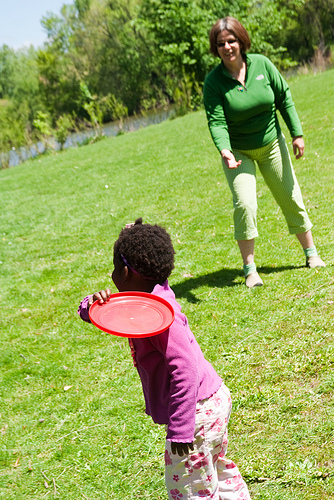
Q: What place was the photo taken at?
A: It was taken at the garden.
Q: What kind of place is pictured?
A: It is a garden.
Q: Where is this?
A: This is at the garden.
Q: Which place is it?
A: It is a garden.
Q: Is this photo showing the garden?
A: Yes, it is showing the garden.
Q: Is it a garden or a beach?
A: It is a garden.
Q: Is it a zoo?
A: No, it is a garden.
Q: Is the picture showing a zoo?
A: No, the picture is showing a garden.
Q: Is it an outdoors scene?
A: Yes, it is outdoors.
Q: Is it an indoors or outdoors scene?
A: It is outdoors.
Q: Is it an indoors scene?
A: No, it is outdoors.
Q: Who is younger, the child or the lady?
A: The child is younger than the lady.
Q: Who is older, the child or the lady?
A: The lady is older than the child.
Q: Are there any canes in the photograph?
A: No, there are no canes.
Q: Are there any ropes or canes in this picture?
A: No, there are no canes or ropes.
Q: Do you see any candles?
A: No, there are no candles.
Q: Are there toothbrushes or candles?
A: No, there are no candles or toothbrushes.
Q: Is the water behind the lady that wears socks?
A: Yes, the water is behind the lady.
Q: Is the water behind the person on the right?
A: Yes, the water is behind the lady.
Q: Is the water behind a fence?
A: No, the water is behind the lady.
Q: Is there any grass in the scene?
A: Yes, there is grass.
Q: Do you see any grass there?
A: Yes, there is grass.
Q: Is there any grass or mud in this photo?
A: Yes, there is grass.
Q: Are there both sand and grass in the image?
A: No, there is grass but no sand.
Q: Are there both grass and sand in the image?
A: No, there is grass but no sand.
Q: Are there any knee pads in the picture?
A: No, there are no knee pads.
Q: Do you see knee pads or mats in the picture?
A: No, there are no knee pads or mats.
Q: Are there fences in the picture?
A: No, there are no fences.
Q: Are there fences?
A: No, there are no fences.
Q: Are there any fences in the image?
A: No, there are no fences.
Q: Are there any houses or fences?
A: No, there are no fences or houses.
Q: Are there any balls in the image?
A: No, there are no balls.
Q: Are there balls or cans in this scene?
A: No, there are no balls or cans.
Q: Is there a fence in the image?
A: No, there are no fences.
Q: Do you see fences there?
A: No, there are no fences.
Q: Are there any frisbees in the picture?
A: Yes, there is a frisbee.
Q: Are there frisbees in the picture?
A: Yes, there is a frisbee.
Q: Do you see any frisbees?
A: Yes, there is a frisbee.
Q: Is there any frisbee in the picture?
A: Yes, there is a frisbee.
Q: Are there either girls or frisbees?
A: Yes, there is a frisbee.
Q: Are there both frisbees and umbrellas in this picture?
A: No, there is a frisbee but no umbrellas.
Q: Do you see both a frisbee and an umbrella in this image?
A: No, there is a frisbee but no umbrellas.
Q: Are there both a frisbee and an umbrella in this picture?
A: No, there is a frisbee but no umbrellas.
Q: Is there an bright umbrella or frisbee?
A: Yes, there is a bright frisbee.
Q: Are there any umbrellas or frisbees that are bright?
A: Yes, the frisbee is bright.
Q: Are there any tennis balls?
A: No, there are no tennis balls.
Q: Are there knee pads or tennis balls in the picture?
A: No, there are no tennis balls or knee pads.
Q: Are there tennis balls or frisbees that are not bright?
A: No, there is a frisbee but it is bright.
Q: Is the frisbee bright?
A: Yes, the frisbee is bright.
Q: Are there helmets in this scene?
A: No, there are no helmets.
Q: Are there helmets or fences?
A: No, there are no helmets or fences.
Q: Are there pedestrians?
A: No, there are no pedestrians.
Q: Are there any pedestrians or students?
A: No, there are no pedestrians or students.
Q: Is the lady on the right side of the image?
A: Yes, the lady is on the right of the image.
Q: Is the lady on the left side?
A: No, the lady is on the right of the image.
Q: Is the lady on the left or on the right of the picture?
A: The lady is on the right of the image.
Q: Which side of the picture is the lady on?
A: The lady is on the right of the image.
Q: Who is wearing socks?
A: The lady is wearing socks.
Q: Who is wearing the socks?
A: The lady is wearing socks.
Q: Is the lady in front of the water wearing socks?
A: Yes, the lady is wearing socks.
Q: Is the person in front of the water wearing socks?
A: Yes, the lady is wearing socks.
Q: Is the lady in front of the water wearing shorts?
A: No, the lady is wearing socks.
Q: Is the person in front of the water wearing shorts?
A: No, the lady is wearing socks.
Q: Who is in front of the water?
A: The lady is in front of the water.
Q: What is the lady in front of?
A: The lady is in front of the water.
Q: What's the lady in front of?
A: The lady is in front of the water.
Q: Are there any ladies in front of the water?
A: Yes, there is a lady in front of the water.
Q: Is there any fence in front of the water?
A: No, there is a lady in front of the water.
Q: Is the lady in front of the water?
A: Yes, the lady is in front of the water.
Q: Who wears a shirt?
A: The lady wears a shirt.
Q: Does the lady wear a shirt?
A: Yes, the lady wears a shirt.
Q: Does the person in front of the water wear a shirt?
A: Yes, the lady wears a shirt.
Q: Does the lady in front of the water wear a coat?
A: No, the lady wears a shirt.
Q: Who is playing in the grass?
A: The lady is playing in the grass.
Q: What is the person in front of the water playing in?
A: The lady is playing in the grass.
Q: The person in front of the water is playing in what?
A: The lady is playing in the grass.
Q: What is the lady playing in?
A: The lady is playing in the grass.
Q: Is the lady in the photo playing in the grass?
A: Yes, the lady is playing in the grass.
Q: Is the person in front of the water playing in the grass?
A: Yes, the lady is playing in the grass.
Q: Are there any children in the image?
A: Yes, there is a child.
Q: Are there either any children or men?
A: Yes, there is a child.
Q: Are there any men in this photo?
A: No, there are no men.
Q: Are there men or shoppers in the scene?
A: No, there are no men or shoppers.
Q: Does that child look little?
A: Yes, the child is little.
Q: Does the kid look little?
A: Yes, the kid is little.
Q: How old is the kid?
A: The kid is little.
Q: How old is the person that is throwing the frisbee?
A: The kid is little.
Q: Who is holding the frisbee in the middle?
A: The kid is holding the frisbee.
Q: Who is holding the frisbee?
A: The kid is holding the frisbee.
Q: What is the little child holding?
A: The child is holding the frisbee.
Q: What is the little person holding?
A: The child is holding the frisbee.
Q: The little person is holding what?
A: The child is holding the frisbee.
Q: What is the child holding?
A: The child is holding the frisbee.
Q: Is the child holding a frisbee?
A: Yes, the child is holding a frisbee.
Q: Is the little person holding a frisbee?
A: Yes, the child is holding a frisbee.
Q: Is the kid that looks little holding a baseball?
A: No, the child is holding a frisbee.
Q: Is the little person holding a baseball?
A: No, the child is holding a frisbee.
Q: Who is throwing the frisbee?
A: The child is throwing the frisbee.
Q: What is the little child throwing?
A: The kid is throwing the frisbee.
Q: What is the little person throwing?
A: The kid is throwing the frisbee.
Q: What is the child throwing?
A: The kid is throwing the frisbee.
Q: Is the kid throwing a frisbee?
A: Yes, the kid is throwing a frisbee.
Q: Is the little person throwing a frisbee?
A: Yes, the kid is throwing a frisbee.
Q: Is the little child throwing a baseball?
A: No, the kid is throwing a frisbee.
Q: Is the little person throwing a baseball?
A: No, the kid is throwing a frisbee.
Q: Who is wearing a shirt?
A: The kid is wearing a shirt.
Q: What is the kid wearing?
A: The kid is wearing a shirt.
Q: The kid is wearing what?
A: The kid is wearing a shirt.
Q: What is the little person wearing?
A: The kid is wearing a shirt.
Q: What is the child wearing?
A: The kid is wearing a shirt.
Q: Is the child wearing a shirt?
A: Yes, the child is wearing a shirt.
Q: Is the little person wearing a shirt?
A: Yes, the child is wearing a shirt.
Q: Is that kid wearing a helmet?
A: No, the kid is wearing a shirt.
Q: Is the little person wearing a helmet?
A: No, the kid is wearing a shirt.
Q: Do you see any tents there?
A: No, there are no tents.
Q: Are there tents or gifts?
A: No, there are no tents or gifts.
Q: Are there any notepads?
A: No, there are no notepads.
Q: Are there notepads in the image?
A: No, there are no notepads.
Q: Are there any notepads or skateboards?
A: No, there are no notepads or skateboards.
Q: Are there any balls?
A: No, there are no balls.